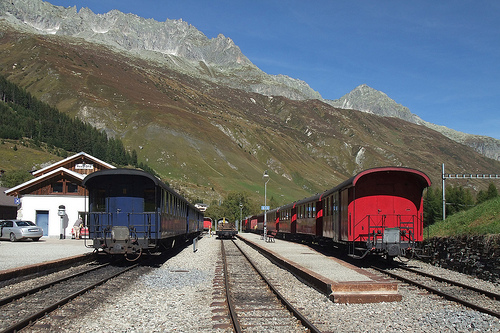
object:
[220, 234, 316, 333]
middle row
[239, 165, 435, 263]
passenger train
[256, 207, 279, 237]
train car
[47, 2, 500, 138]
sky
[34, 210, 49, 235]
door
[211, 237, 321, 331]
track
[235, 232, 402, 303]
median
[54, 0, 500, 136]
cloud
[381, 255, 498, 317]
track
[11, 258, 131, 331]
track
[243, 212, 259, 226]
passenger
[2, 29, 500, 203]
hill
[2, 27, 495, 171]
slope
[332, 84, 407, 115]
mountaintop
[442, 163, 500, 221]
lights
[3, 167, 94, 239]
building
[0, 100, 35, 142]
trees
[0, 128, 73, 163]
slope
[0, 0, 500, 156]
mountain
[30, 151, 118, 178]
building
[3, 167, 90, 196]
roofs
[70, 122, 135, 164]
trees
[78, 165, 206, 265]
blue train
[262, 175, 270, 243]
pole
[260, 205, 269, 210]
sign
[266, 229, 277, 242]
bench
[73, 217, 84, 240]
person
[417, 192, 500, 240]
hill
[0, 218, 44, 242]
car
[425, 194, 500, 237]
grass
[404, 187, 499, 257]
slope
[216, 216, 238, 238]
train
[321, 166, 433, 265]
red caboose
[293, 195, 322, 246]
train car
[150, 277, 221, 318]
gravel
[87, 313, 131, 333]
pebbles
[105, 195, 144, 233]
paint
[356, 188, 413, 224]
paint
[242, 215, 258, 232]
passenger car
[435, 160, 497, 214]
structure